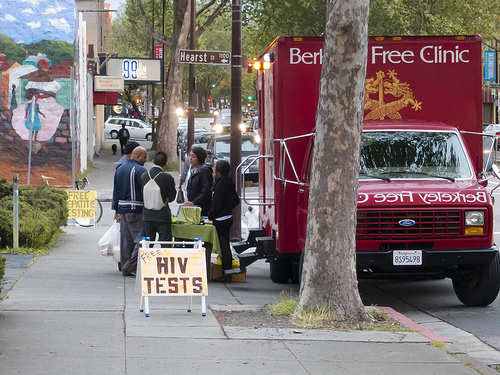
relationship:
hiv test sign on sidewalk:
[136, 240, 211, 302] [1, 145, 495, 375]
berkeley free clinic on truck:
[282, 46, 473, 68] [252, 27, 500, 307]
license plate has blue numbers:
[391, 247, 424, 267] [394, 254, 421, 264]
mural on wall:
[1, 1, 80, 187] [1, 0, 86, 187]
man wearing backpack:
[138, 149, 177, 247] [145, 170, 166, 211]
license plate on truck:
[391, 247, 424, 267] [252, 27, 500, 307]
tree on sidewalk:
[287, 2, 372, 328] [1, 145, 495, 375]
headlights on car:
[210, 120, 247, 134] [205, 108, 248, 139]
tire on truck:
[452, 248, 500, 304] [252, 27, 500, 307]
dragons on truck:
[358, 66, 425, 123] [252, 27, 500, 307]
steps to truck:
[226, 228, 277, 279] [252, 27, 500, 307]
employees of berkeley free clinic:
[178, 144, 236, 284] [282, 46, 473, 68]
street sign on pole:
[176, 50, 235, 66] [227, 2, 242, 242]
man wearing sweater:
[138, 149, 177, 247] [141, 165, 175, 223]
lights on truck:
[455, 208, 491, 238] [252, 27, 500, 307]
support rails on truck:
[231, 147, 275, 210] [252, 27, 500, 307]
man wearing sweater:
[109, 144, 152, 278] [111, 158, 150, 209]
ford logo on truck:
[396, 215, 419, 229] [252, 27, 500, 307]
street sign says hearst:
[176, 50, 235, 66] [180, 53, 209, 62]